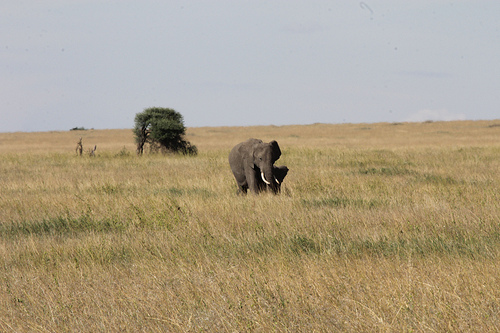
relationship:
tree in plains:
[131, 106, 188, 155] [25, 136, 484, 314]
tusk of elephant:
[260, 170, 270, 184] [224, 129, 285, 199]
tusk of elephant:
[272, 165, 282, 190] [224, 129, 285, 199]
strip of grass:
[3, 220, 483, 276] [6, 215, 484, 270]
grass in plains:
[6, 215, 484, 270] [25, 136, 484, 314]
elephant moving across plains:
[225, 132, 288, 193] [25, 136, 484, 314]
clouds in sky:
[34, 30, 90, 77] [9, 3, 484, 122]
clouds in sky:
[408, 26, 467, 99] [51, 15, 484, 121]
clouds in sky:
[135, 39, 210, 103] [48, 9, 405, 104]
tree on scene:
[134, 104, 200, 158] [5, 15, 483, 300]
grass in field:
[25, 199, 484, 305] [20, 132, 480, 312]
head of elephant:
[252, 140, 280, 174] [222, 135, 285, 195]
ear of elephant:
[238, 138, 263, 169] [222, 135, 285, 195]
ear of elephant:
[266, 133, 287, 163] [222, 135, 285, 195]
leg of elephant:
[237, 176, 247, 197] [225, 136, 285, 204]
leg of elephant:
[244, 162, 263, 196] [225, 136, 285, 204]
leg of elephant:
[260, 168, 280, 198] [225, 136, 285, 204]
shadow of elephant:
[272, 158, 302, 198] [224, 129, 285, 199]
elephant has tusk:
[226, 137, 285, 196] [256, 165, 271, 185]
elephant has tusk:
[226, 137, 285, 196] [272, 171, 283, 186]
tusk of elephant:
[258, 168, 269, 187] [226, 131, 280, 195]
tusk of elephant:
[273, 175, 279, 184] [226, 131, 280, 195]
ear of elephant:
[269, 140, 281, 164] [230, 135, 287, 201]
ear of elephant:
[240, 138, 260, 169] [224, 129, 285, 199]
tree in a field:
[131, 106, 188, 155] [24, 104, 467, 309]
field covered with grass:
[20, 132, 480, 312] [18, 125, 458, 313]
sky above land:
[1, 1, 497, 138] [1, 119, 498, 331]